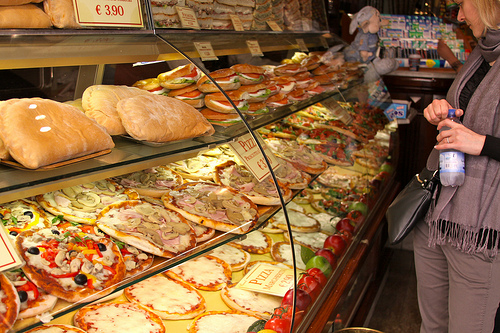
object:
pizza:
[82, 305, 162, 333]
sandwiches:
[272, 63, 308, 78]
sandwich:
[313, 73, 338, 86]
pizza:
[126, 271, 204, 318]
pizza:
[169, 254, 231, 291]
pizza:
[223, 285, 285, 317]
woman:
[389, 0, 500, 333]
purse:
[384, 156, 441, 245]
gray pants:
[411, 185, 497, 333]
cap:
[447, 109, 457, 117]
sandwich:
[157, 62, 201, 90]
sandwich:
[230, 62, 264, 84]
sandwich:
[203, 90, 249, 113]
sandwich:
[170, 83, 205, 107]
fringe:
[467, 229, 479, 255]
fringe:
[426, 220, 437, 251]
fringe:
[449, 223, 460, 248]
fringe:
[483, 226, 489, 253]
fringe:
[436, 219, 446, 247]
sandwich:
[275, 63, 308, 78]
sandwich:
[238, 83, 273, 102]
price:
[228, 131, 281, 184]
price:
[235, 260, 303, 299]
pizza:
[10, 221, 128, 302]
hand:
[434, 118, 487, 156]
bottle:
[437, 108, 466, 187]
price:
[93, 4, 126, 21]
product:
[42, 0, 84, 27]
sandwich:
[195, 68, 241, 93]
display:
[0, 0, 403, 333]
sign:
[194, 41, 217, 61]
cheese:
[184, 259, 224, 285]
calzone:
[2, 95, 117, 170]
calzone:
[116, 92, 216, 145]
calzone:
[79, 82, 151, 136]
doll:
[342, 3, 384, 65]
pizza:
[189, 306, 258, 333]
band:
[447, 137, 451, 144]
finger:
[437, 137, 456, 142]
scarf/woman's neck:
[476, 33, 498, 71]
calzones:
[1, 6, 50, 30]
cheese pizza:
[312, 142, 353, 167]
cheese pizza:
[296, 127, 345, 148]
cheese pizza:
[323, 116, 369, 145]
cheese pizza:
[256, 122, 301, 140]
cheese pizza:
[281, 114, 317, 129]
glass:
[283, 104, 304, 114]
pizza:
[93, 195, 200, 262]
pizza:
[160, 180, 256, 236]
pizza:
[213, 161, 291, 204]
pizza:
[121, 266, 208, 321]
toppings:
[191, 191, 225, 211]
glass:
[114, 146, 152, 158]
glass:
[0, 165, 28, 186]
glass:
[201, 238, 223, 251]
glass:
[215, 126, 240, 144]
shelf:
[0, 24, 399, 333]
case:
[0, 0, 408, 333]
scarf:
[421, 42, 500, 259]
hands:
[422, 98, 464, 125]